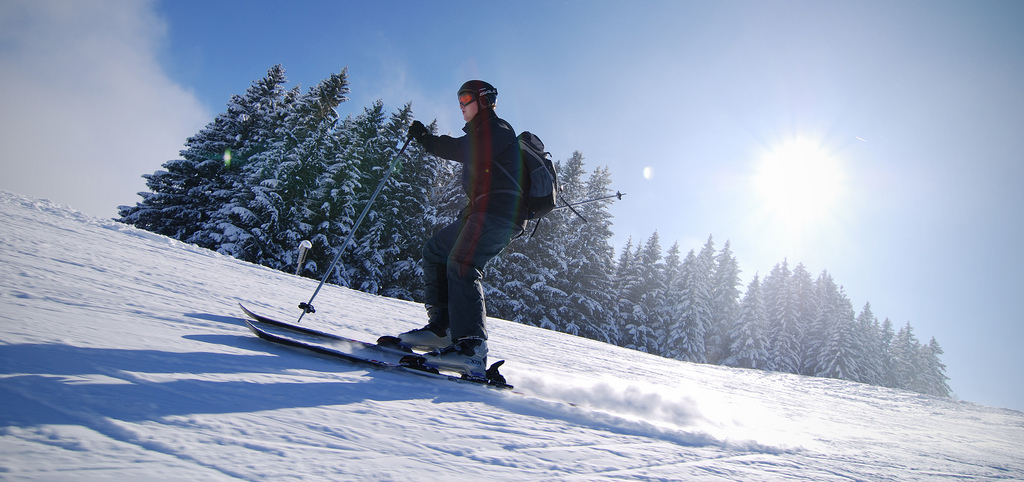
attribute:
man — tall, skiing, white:
[247, 67, 625, 414]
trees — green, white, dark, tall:
[156, 34, 953, 383]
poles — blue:
[297, 125, 431, 328]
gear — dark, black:
[427, 131, 561, 326]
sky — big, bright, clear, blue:
[2, 6, 1024, 262]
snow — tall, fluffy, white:
[9, 200, 1018, 479]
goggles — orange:
[456, 92, 479, 109]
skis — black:
[253, 308, 524, 408]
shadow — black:
[4, 306, 362, 437]